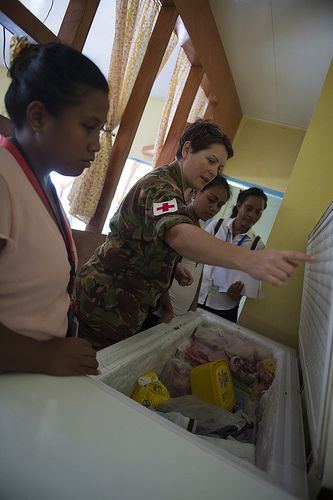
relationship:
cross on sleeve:
[154, 202, 175, 211] [141, 164, 191, 248]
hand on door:
[248, 248, 318, 288] [296, 200, 331, 488]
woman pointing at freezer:
[73, 117, 316, 349] [84, 204, 332, 498]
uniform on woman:
[73, 157, 197, 354] [73, 117, 316, 349]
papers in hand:
[211, 264, 264, 300] [227, 280, 248, 302]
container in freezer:
[190, 359, 238, 413] [84, 204, 332, 498]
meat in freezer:
[161, 357, 195, 399] [84, 204, 332, 498]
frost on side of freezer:
[255, 350, 280, 473] [84, 204, 332, 498]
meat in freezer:
[187, 339, 221, 363] [84, 204, 332, 498]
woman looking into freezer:
[73, 117, 316, 349] [84, 204, 332, 498]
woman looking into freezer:
[2, 36, 109, 379] [84, 204, 332, 498]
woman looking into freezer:
[168, 170, 231, 315] [84, 204, 332, 498]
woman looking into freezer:
[196, 188, 268, 320] [84, 204, 332, 498]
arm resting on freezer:
[0, 324, 102, 382] [2, 375, 302, 500]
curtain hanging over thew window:
[66, 3, 165, 226] [50, 1, 164, 232]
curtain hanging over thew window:
[152, 47, 193, 167] [103, 44, 191, 234]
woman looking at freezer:
[2, 36, 109, 379] [84, 204, 332, 498]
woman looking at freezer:
[168, 170, 231, 315] [84, 204, 332, 498]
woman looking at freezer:
[73, 117, 316, 349] [84, 204, 332, 498]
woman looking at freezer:
[196, 188, 268, 320] [84, 204, 332, 498]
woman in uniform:
[73, 117, 316, 349] [73, 157, 197, 354]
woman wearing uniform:
[73, 117, 316, 349] [73, 157, 197, 354]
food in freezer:
[192, 326, 257, 361] [84, 204, 332, 498]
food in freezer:
[230, 355, 254, 383] [84, 204, 332, 498]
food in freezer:
[154, 396, 252, 444] [84, 204, 332, 498]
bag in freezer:
[129, 370, 172, 408] [84, 204, 332, 498]